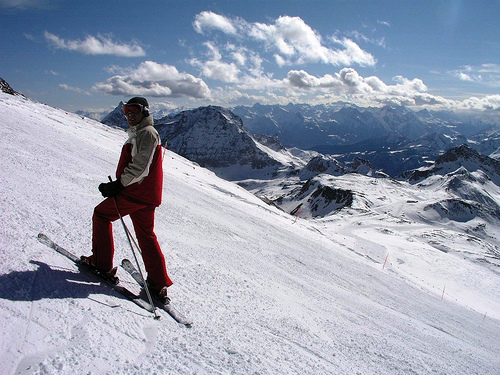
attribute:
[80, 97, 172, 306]
skier — skiing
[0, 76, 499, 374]
hill — snowy, steep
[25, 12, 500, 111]
clouds — white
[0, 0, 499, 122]
sky — blue, cloudy, large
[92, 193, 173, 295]
pants — red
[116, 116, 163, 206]
jacket — red, white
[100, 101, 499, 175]
mountains — snowy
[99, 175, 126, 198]
gloves — black